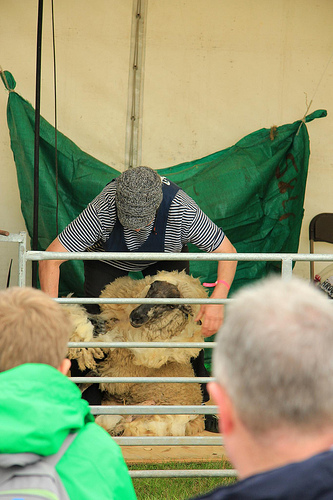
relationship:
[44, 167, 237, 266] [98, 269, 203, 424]
man sheering sheep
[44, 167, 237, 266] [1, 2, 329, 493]
man in photo